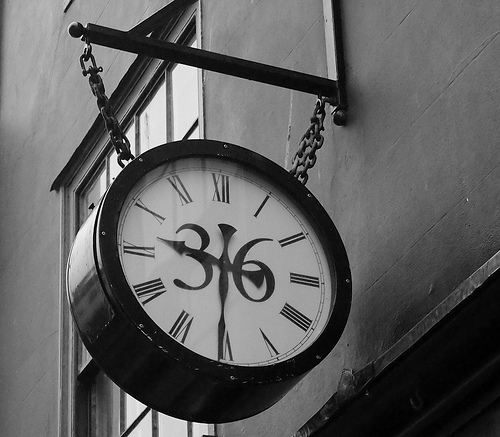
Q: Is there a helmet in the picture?
A: No, there are no helmets.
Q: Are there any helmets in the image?
A: No, there are no helmets.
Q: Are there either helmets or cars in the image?
A: No, there are no helmets or cars.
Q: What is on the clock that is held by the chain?
A: The number is on the clock.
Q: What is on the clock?
A: The number is on the clock.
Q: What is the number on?
A: The number is on the clock.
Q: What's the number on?
A: The number is on the clock.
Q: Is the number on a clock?
A: Yes, the number is on a clock.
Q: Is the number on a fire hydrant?
A: No, the number is on a clock.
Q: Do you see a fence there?
A: No, there are no fences.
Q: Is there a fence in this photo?
A: No, there are no fences.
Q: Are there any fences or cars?
A: No, there are no fences or cars.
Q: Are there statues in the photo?
A: No, there are no statues.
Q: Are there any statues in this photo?
A: No, there are no statues.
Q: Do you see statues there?
A: No, there are no statues.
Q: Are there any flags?
A: No, there are no flags.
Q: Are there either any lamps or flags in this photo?
A: No, there are no flags or lamps.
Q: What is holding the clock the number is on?
A: The chain is holding the clock.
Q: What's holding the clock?
A: The chain is holding the clock.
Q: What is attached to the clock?
A: The chain is attached to the clock.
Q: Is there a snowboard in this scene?
A: No, there are no snowboards.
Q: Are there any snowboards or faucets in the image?
A: No, there are no snowboards or faucets.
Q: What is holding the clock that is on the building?
A: The chain is holding the clock.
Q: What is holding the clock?
A: The chain is holding the clock.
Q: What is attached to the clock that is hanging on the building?
A: The chain is attached to the clock.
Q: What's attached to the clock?
A: The chain is attached to the clock.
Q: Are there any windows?
A: Yes, there is a window.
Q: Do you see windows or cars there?
A: Yes, there is a window.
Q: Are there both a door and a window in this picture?
A: No, there is a window but no doors.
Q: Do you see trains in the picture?
A: No, there are no trains.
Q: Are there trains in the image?
A: No, there are no trains.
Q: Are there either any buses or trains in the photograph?
A: No, there are no trains or buses.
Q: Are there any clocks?
A: Yes, there is a clock.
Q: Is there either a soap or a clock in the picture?
A: Yes, there is a clock.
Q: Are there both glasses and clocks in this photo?
A: No, there is a clock but no glasses.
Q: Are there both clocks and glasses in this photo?
A: No, there is a clock but no glasses.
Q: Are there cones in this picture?
A: No, there are no cones.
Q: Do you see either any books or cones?
A: No, there are no cones or books.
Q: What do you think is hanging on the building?
A: The clock is hanging on the building.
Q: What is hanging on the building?
A: The clock is hanging on the building.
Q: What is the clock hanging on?
A: The clock is hanging on the building.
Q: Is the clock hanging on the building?
A: Yes, the clock is hanging on the building.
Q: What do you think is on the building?
A: The clock is on the building.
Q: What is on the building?
A: The clock is on the building.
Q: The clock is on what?
A: The clock is on the building.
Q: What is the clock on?
A: The clock is on the building.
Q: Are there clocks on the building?
A: Yes, there is a clock on the building.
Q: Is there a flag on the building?
A: No, there is a clock on the building.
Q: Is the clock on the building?
A: Yes, the clock is on the building.